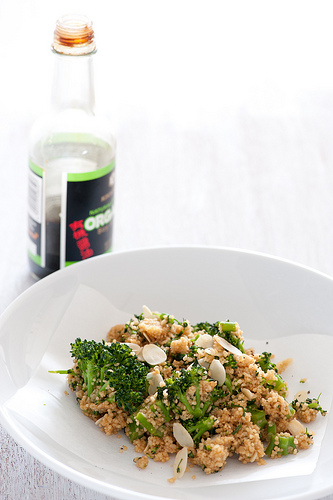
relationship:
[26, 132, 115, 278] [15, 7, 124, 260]
label on bottle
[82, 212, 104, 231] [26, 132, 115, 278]
letters on label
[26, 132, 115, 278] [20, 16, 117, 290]
label for bottle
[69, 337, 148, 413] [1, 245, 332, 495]
broccoli in bowl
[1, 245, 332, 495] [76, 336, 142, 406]
bowl with broocoli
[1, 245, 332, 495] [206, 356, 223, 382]
bowl with almonds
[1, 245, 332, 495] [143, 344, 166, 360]
bowl with almonds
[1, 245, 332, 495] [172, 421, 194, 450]
bowl with almonds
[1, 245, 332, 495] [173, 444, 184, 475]
bowl with almonds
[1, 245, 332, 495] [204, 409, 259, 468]
bowl with quinoa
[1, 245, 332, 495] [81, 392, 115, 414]
bowl with quinoa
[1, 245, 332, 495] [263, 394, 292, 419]
bowl with quinoa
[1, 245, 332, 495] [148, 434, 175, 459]
bowl with quinoa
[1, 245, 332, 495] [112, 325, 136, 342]
bowl with quinoa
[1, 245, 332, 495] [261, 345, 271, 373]
bowl with brocolli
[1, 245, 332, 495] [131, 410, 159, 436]
bowl with brocolli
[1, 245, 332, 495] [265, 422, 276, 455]
bowl with brocolli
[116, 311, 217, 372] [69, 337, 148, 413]
almonds to right of broccoli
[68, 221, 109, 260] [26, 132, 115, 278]
symbols running down label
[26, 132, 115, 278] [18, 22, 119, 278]
label on bottle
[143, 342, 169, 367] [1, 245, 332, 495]
almonds in bowl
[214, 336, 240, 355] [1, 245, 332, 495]
almonds in bowl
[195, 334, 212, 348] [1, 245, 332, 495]
almonds in bowl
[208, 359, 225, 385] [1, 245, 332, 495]
almonds in bowl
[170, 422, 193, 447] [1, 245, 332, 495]
almonds in bowl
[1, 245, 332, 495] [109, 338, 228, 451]
bowl with food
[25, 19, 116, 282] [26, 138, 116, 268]
bottle with label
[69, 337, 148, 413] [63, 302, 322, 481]
broccoli in meal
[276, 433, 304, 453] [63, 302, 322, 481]
celery in meal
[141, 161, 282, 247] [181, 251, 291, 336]
table under bowl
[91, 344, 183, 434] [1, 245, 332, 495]
broccoli on bowl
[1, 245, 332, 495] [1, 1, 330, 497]
bowl on counter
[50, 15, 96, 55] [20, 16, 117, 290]
top for bottle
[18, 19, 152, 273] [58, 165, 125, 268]
bottle with label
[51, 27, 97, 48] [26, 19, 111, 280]
sauce around opening of bottle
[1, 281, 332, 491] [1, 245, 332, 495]
napkin in bowl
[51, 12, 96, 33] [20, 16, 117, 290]
dispensing region on bottle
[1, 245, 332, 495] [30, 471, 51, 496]
bowl on table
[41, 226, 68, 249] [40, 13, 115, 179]
condiment in bottle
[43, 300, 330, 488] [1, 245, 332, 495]
food on bowl